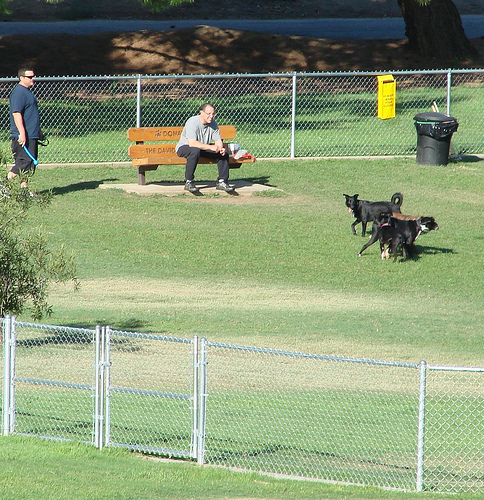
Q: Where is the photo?
A: Park.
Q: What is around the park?
A: Fence.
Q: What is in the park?
A: Dogs.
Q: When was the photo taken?
A: Noon.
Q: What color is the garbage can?
A: Black.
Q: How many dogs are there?
A: Three.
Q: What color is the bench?
A: Brown.